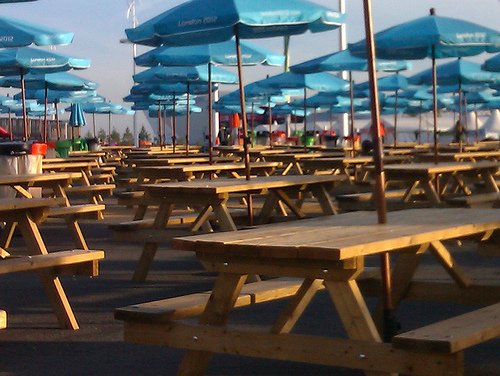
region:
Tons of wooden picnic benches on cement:
[0, 139, 499, 374]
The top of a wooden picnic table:
[195, 200, 497, 256]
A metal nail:
[358, 352, 364, 359]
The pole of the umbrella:
[229, 31, 271, 223]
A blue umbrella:
[124, 1, 347, 46]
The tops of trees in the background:
[85, 125, 157, 151]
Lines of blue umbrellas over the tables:
[1, 6, 452, 136]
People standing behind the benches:
[212, 105, 392, 157]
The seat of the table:
[114, 262, 317, 341]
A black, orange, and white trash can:
[2, 139, 51, 202]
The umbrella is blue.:
[0, 8, 83, 53]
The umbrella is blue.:
[0, 42, 92, 89]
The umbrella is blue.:
[124, 60, 246, 97]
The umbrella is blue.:
[340, 7, 499, 97]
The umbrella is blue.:
[291, 42, 415, 82]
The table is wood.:
[101, 168, 361, 302]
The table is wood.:
[111, 193, 498, 375]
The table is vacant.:
[104, 195, 498, 373]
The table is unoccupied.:
[111, 191, 497, 372]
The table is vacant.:
[96, 154, 358, 284]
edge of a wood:
[228, 306, 258, 349]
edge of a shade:
[70, 322, 92, 357]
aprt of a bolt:
[200, 333, 219, 355]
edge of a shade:
[118, 343, 148, 371]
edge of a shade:
[94, 337, 117, 359]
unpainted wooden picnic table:
[114, 204, 494, 366]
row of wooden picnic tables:
[126, 129, 357, 374]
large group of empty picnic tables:
[131, 126, 498, 211]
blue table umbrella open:
[123, 1, 347, 48]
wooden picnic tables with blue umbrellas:
[120, 2, 343, 357]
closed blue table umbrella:
[67, 98, 86, 140]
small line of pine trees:
[92, 124, 152, 147]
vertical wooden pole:
[230, 29, 258, 181]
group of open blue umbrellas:
[8, 1, 498, 126]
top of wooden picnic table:
[171, 206, 497, 266]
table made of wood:
[116, 205, 498, 375]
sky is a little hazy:
[0, 2, 498, 143]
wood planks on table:
[178, 205, 498, 261]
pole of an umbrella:
[362, 0, 394, 324]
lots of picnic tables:
[0, 142, 498, 374]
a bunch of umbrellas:
[1, 0, 496, 127]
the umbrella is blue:
[126, 0, 343, 44]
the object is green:
[57, 139, 87, 155]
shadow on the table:
[285, 209, 499, 226]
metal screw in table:
[358, 352, 365, 359]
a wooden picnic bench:
[233, 214, 472, 373]